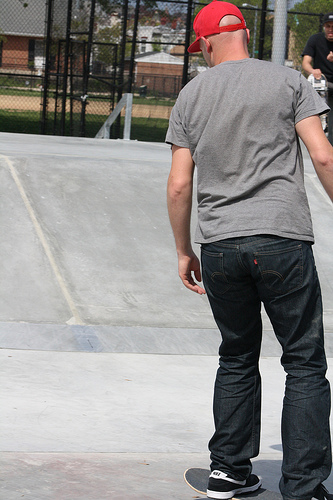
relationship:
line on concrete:
[3, 152, 82, 324] [0, 133, 330, 498]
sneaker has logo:
[207, 470, 262, 499] [212, 471, 221, 479]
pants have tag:
[201, 234, 332, 499] [253, 258, 260, 264]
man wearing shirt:
[168, 0, 332, 499] [164, 59, 331, 245]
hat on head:
[187, 0, 246, 53] [201, 2, 252, 66]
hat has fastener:
[187, 0, 246, 53] [218, 24, 247, 32]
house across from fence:
[1, 1, 92, 84] [3, 2, 332, 142]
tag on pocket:
[253, 258, 260, 264] [254, 248, 301, 291]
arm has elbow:
[166, 94, 202, 293] [167, 175, 192, 206]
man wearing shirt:
[303, 14, 332, 141] [302, 33, 333, 81]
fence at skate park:
[3, 2, 332, 142] [3, 4, 332, 500]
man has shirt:
[168, 0, 332, 499] [164, 59, 331, 245]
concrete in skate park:
[0, 133, 330, 498] [3, 4, 332, 500]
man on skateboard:
[168, 0, 332, 499] [184, 467, 285, 499]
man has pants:
[168, 0, 332, 499] [201, 234, 332, 499]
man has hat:
[168, 0, 332, 499] [187, 0, 246, 53]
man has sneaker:
[168, 0, 332, 499] [207, 470, 262, 499]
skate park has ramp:
[3, 4, 332, 500] [3, 156, 330, 353]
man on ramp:
[303, 14, 332, 141] [3, 156, 330, 353]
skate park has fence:
[3, 4, 332, 500] [3, 2, 332, 142]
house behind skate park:
[1, 1, 92, 84] [3, 4, 332, 500]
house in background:
[1, 1, 92, 84] [0, 0, 332, 142]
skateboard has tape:
[184, 467, 285, 499] [187, 467, 297, 500]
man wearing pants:
[168, 0, 332, 499] [201, 234, 332, 499]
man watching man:
[303, 14, 332, 141] [168, 0, 332, 499]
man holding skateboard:
[303, 14, 332, 141] [308, 73, 327, 138]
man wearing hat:
[168, 0, 332, 499] [187, 0, 246, 53]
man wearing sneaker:
[168, 0, 332, 499] [207, 470, 262, 499]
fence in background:
[3, 2, 332, 142] [0, 0, 332, 142]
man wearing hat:
[303, 14, 332, 141] [322, 15, 332, 25]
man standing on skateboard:
[168, 0, 332, 499] [184, 467, 285, 499]